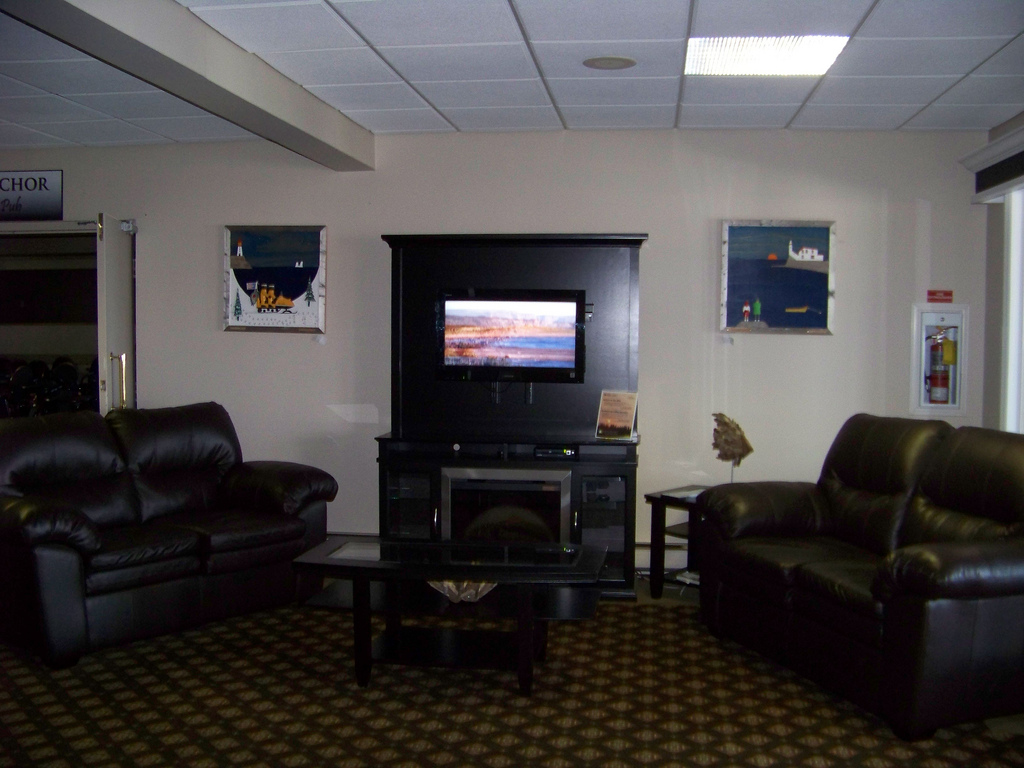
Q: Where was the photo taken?
A: It was taken at the living room.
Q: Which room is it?
A: It is a living room.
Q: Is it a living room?
A: Yes, it is a living room.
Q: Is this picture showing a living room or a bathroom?
A: It is showing a living room.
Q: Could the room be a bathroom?
A: No, it is a living room.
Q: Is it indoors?
A: Yes, it is indoors.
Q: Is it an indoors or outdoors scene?
A: It is indoors.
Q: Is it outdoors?
A: No, it is indoors.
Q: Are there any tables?
A: Yes, there is a table.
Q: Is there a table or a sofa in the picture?
A: Yes, there is a table.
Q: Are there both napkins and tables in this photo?
A: No, there is a table but no napkins.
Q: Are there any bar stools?
A: No, there are no bar stools.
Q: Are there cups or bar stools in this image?
A: No, there are no bar stools or cups.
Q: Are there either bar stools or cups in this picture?
A: No, there are no bar stools or cups.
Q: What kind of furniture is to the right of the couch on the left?
A: The piece of furniture is a table.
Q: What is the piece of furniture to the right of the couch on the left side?
A: The piece of furniture is a table.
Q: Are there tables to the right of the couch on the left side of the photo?
A: Yes, there is a table to the right of the couch.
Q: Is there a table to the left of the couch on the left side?
A: No, the table is to the right of the couch.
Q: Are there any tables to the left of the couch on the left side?
A: No, the table is to the right of the couch.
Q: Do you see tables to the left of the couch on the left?
A: No, the table is to the right of the couch.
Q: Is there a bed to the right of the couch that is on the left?
A: No, there is a table to the right of the couch.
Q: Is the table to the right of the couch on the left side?
A: Yes, the table is to the right of the couch.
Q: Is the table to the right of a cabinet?
A: No, the table is to the right of the couch.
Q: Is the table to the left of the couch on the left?
A: No, the table is to the right of the couch.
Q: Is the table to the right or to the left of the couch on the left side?
A: The table is to the right of the couch.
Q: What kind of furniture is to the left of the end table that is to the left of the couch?
A: The piece of furniture is a table.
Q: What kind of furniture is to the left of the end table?
A: The piece of furniture is a table.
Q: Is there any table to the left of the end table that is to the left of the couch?
A: Yes, there is a table to the left of the end table.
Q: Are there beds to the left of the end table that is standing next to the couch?
A: No, there is a table to the left of the end table.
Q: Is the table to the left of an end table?
A: Yes, the table is to the left of an end table.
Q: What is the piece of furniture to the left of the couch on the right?
A: The piece of furniture is a table.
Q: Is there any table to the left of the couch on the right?
A: Yes, there is a table to the left of the couch.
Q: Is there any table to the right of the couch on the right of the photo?
A: No, the table is to the left of the couch.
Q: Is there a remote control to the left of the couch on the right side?
A: No, there is a table to the left of the couch.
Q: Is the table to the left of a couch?
A: Yes, the table is to the left of a couch.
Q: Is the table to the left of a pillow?
A: No, the table is to the left of a couch.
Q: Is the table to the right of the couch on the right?
A: No, the table is to the left of the couch.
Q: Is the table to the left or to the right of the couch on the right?
A: The table is to the left of the couch.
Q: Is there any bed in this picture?
A: No, there are no beds.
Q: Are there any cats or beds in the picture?
A: No, there are no beds or cats.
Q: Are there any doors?
A: Yes, there is a door.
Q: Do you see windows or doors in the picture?
A: Yes, there is a door.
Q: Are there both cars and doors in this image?
A: No, there is a door but no cars.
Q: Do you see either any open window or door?
A: Yes, there is an open door.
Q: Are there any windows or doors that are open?
A: Yes, the door is open.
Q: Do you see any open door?
A: Yes, there is an open door.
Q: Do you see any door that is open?
A: Yes, there is an open door.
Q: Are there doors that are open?
A: Yes, there is a door that is open.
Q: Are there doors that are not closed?
A: Yes, there is a open door.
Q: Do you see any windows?
A: No, there are no windows.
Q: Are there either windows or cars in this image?
A: No, there are no windows or cars.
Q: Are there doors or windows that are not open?
A: No, there is a door but it is open.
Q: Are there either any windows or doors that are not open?
A: No, there is a door but it is open.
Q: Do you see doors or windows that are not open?
A: No, there is a door but it is open.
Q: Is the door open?
A: Yes, the door is open.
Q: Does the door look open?
A: Yes, the door is open.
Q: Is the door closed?
A: No, the door is open.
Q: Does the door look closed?
A: No, the door is open.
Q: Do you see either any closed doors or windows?
A: No, there is a door but it is open.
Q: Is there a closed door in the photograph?
A: No, there is a door but it is open.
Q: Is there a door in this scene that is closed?
A: No, there is a door but it is open.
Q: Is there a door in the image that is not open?
A: No, there is a door but it is open.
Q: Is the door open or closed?
A: The door is open.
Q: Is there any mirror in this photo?
A: No, there are no mirrors.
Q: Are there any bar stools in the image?
A: No, there are no bar stools.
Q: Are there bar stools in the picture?
A: No, there are no bar stools.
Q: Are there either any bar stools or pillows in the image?
A: No, there are no bar stools or pillows.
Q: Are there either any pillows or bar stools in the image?
A: No, there are no bar stools or pillows.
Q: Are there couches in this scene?
A: Yes, there is a couch.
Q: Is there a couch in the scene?
A: Yes, there is a couch.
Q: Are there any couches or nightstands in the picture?
A: Yes, there is a couch.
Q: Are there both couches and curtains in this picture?
A: No, there is a couch but no curtains.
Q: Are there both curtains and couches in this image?
A: No, there is a couch but no curtains.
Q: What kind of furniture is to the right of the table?
A: The piece of furniture is a couch.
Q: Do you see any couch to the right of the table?
A: Yes, there is a couch to the right of the table.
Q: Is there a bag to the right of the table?
A: No, there is a couch to the right of the table.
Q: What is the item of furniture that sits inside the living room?
A: The piece of furniture is a couch.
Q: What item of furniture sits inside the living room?
A: The piece of furniture is a couch.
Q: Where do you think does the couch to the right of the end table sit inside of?
A: The couch sits inside the living room.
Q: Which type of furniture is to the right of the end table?
A: The piece of furniture is a couch.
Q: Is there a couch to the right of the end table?
A: Yes, there is a couch to the right of the end table.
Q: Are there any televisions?
A: Yes, there is a television.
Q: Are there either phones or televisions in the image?
A: Yes, there is a television.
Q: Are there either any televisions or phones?
A: Yes, there is a television.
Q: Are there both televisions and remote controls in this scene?
A: No, there is a television but no remote controls.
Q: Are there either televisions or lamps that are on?
A: Yes, the television is on.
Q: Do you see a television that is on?
A: Yes, there is a television that is on.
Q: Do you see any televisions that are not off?
A: Yes, there is a television that is on .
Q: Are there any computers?
A: No, there are no computers.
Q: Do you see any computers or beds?
A: No, there are no computers or beds.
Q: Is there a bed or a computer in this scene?
A: No, there are no computers or beds.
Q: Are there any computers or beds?
A: No, there are no computers or beds.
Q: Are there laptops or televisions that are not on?
A: No, there is a television but it is on.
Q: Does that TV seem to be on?
A: Yes, the TV is on.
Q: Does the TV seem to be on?
A: Yes, the TV is on.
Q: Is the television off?
A: No, the television is on.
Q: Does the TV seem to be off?
A: No, the TV is on.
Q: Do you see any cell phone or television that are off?
A: No, there is a television but it is on.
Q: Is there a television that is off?
A: No, there is a television but it is on.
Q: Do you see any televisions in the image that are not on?
A: No, there is a television but it is on.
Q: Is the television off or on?
A: The television is on.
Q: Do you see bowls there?
A: No, there are no bowls.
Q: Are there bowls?
A: No, there are no bowls.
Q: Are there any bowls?
A: No, there are no bowls.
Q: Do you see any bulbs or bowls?
A: No, there are no bowls or bulbs.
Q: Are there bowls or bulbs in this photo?
A: No, there are no bowls or bulbs.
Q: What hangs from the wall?
A: The painting hangs from the wall.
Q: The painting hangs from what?
A: The painting hangs from the wall.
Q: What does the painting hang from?
A: The painting hangs from the wall.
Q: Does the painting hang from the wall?
A: Yes, the painting hangs from the wall.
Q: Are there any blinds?
A: No, there are no blinds.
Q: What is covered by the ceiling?
A: The living room is covered by the ceiling.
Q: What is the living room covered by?
A: The living room is covered by the ceiling.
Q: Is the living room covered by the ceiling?
A: Yes, the living room is covered by the ceiling.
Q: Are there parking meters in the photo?
A: No, there are no parking meters.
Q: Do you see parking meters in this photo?
A: No, there are no parking meters.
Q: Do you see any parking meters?
A: No, there are no parking meters.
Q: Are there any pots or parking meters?
A: No, there are no parking meters or pots.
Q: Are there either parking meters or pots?
A: No, there are no parking meters or pots.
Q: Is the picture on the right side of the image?
A: Yes, the picture is on the right of the image.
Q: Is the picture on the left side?
A: No, the picture is on the right of the image.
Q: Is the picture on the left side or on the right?
A: The picture is on the right of the image.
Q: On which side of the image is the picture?
A: The picture is on the right of the image.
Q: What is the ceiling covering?
A: The ceiling is covering the living room.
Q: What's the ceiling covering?
A: The ceiling is covering the living room.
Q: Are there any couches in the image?
A: Yes, there is a couch.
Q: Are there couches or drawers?
A: Yes, there is a couch.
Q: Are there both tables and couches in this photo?
A: Yes, there are both a couch and a table.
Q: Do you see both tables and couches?
A: Yes, there are both a couch and a table.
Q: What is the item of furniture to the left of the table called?
A: The piece of furniture is a couch.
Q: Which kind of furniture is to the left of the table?
A: The piece of furniture is a couch.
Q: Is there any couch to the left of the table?
A: Yes, there is a couch to the left of the table.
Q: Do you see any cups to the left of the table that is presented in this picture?
A: No, there is a couch to the left of the table.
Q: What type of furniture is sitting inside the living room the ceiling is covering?
A: The piece of furniture is a couch.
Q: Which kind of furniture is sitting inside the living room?
A: The piece of furniture is a couch.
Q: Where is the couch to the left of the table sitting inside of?
A: The couch is sitting inside the living room.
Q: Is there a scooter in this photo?
A: No, there are no scooters.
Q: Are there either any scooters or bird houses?
A: No, there are no scooters or bird houses.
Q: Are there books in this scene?
A: No, there are no books.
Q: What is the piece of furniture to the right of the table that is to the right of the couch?
A: The piece of furniture is an end table.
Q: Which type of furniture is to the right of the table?
A: The piece of furniture is an end table.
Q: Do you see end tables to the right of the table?
A: Yes, there is an end table to the right of the table.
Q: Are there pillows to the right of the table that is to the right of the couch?
A: No, there is an end table to the right of the table.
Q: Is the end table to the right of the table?
A: Yes, the end table is to the right of the table.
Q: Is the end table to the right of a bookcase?
A: No, the end table is to the right of the table.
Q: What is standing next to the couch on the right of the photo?
A: The end table is standing next to the couch.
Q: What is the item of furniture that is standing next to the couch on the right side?
A: The piece of furniture is an end table.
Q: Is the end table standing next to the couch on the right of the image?
A: Yes, the end table is standing next to the couch.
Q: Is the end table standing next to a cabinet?
A: No, the end table is standing next to the couch.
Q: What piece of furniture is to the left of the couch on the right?
A: The piece of furniture is an end table.